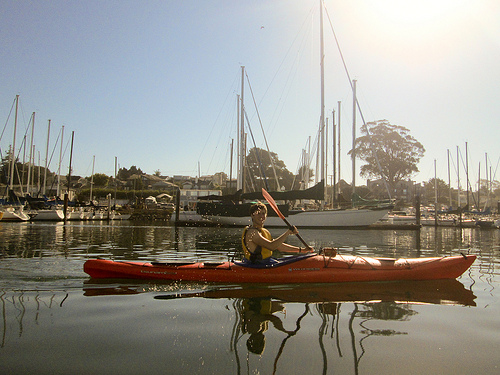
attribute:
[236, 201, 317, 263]
man — reflected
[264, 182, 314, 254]
rowing stick — red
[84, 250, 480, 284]
boat — red, white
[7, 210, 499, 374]
water — anchored, clear, calm, brownish, splahing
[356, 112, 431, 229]
tree — green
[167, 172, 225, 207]
building — white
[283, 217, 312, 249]
handle — black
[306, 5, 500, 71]
sun — bright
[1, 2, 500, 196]
sky — blue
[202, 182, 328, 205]
sail — black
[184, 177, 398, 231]
boat — parked, white